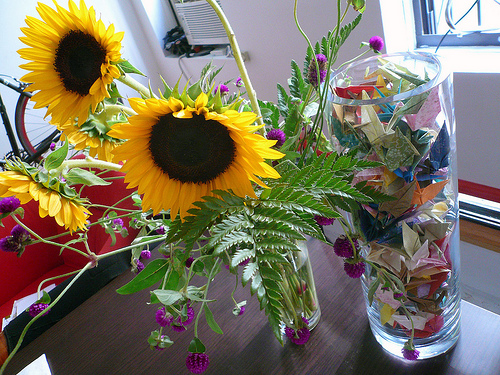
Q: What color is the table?
A: Brown.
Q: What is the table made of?
A: Wood.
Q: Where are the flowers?
A: In a vase.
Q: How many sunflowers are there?
A: Four.